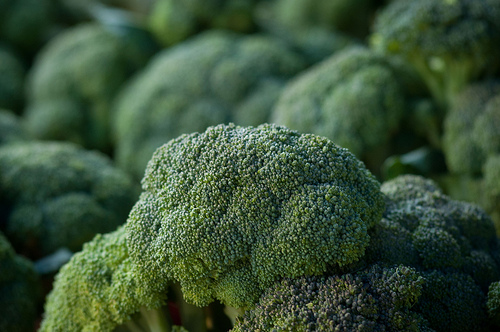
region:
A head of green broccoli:
[135, 123, 356, 291]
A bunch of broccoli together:
[31, 29, 460, 306]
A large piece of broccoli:
[136, 122, 348, 279]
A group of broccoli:
[78, 122, 446, 322]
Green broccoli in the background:
[38, 30, 291, 117]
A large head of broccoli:
[138, 123, 358, 281]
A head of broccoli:
[53, 230, 124, 320]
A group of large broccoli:
[26, 37, 449, 326]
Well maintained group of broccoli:
[53, 131, 416, 327]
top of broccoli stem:
[280, 174, 377, 275]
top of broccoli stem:
[60, 218, 167, 327]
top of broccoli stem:
[131, 120, 239, 327]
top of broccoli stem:
[38, 139, 113, 252]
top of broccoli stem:
[130, 50, 239, 137]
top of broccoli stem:
[225, 18, 307, 123]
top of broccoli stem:
[316, 31, 403, 163]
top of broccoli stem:
[393, 161, 473, 275]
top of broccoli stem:
[60, 26, 123, 130]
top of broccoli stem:
[269, 236, 365, 324]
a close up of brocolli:
[3, 3, 498, 330]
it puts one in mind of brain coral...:
[143, 110, 377, 299]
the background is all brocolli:
[43, 16, 470, 127]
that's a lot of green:
[16, 12, 483, 327]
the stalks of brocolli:
[126, 303, 236, 328]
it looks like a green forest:
[16, 5, 498, 327]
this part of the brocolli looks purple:
[288, 268, 413, 330]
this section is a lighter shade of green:
[48, 235, 139, 326]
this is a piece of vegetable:
[125, 150, 194, 229]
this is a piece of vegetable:
[39, 246, 169, 311]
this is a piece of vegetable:
[151, 130, 368, 275]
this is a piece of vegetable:
[14, 131, 120, 243]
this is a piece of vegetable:
[115, 38, 298, 154]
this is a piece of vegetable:
[282, 33, 416, 168]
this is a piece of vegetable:
[40, 28, 147, 138]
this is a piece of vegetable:
[450, 93, 491, 191]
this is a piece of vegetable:
[146, 139, 256, 288]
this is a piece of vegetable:
[36, 243, 160, 326]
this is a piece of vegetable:
[263, 188, 368, 270]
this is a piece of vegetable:
[369, 245, 443, 327]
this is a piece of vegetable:
[274, 256, 376, 328]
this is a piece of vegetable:
[289, 52, 406, 169]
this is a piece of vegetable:
[399, 158, 492, 260]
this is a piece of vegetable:
[104, 53, 252, 153]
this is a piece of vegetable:
[19, 17, 126, 133]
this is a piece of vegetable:
[141, 7, 318, 139]